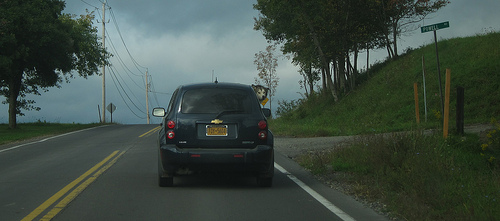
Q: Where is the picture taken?
A: The road.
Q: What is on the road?
A: Car.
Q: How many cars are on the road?
A: One.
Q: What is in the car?
A: Dog.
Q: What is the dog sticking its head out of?
A: Window.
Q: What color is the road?
A: Black.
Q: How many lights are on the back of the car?
A: 4.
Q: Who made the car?
A: Chevy.